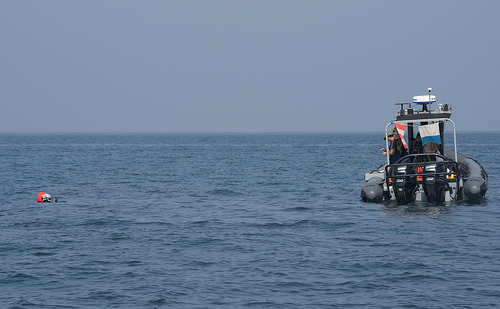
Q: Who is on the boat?
A: Fisherman.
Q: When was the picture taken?
A: Daytime.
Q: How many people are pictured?
A: 1.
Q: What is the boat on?
A: Water.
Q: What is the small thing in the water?
A: Buoy.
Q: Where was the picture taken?
A: Ocean.